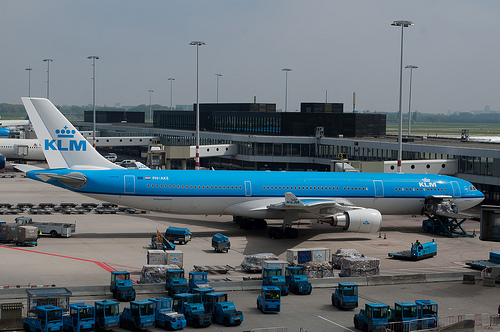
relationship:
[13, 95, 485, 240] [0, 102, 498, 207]
plane pulled up to terminal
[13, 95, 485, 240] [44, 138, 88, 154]
plane says klm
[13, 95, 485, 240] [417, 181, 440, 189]
plane says klm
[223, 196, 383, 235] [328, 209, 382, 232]
wing has engine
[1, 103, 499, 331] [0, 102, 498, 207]
airport has terminal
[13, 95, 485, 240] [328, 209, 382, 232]
plane has engine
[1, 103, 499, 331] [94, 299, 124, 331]
airport has transport car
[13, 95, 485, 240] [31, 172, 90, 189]
plane has wing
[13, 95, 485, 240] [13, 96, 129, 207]
plane has tail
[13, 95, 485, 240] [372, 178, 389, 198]
plane has door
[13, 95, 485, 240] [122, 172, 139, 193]
plane has door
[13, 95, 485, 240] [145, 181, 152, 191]
plane has window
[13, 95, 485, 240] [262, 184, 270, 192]
plane has window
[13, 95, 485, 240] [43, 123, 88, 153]
plane has logo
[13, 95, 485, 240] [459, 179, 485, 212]
plane has nose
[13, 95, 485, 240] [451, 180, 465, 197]
plane has door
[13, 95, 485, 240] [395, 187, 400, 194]
plane has window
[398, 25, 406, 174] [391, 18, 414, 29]
pole has lights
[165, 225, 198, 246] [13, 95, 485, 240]
cart near plane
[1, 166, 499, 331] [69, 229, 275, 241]
tarmac has shadow